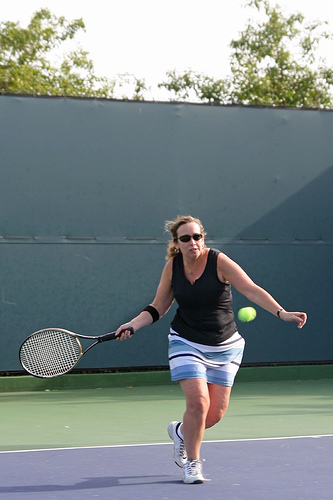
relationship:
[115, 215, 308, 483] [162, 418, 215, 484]
woman wears shoes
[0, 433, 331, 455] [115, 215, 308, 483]
line behind woman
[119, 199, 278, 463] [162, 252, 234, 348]
woman wearing shirt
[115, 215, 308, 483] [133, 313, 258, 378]
woman wearing skirt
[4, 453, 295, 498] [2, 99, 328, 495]
paint on court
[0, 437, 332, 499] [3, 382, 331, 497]
paint on court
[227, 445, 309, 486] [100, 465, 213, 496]
purple paint on court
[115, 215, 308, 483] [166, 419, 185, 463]
woman wearing shoe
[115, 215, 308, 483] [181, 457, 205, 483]
woman wearing shoe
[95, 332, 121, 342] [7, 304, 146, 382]
black grip on racket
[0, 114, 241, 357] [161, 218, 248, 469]
wall behind woman